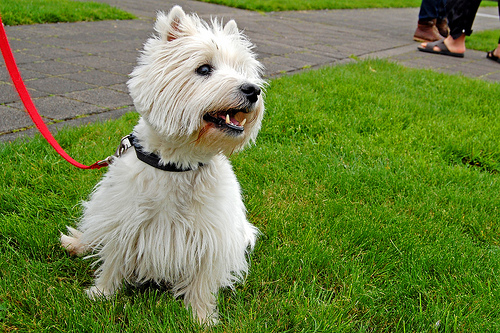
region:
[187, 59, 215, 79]
the dog's right eye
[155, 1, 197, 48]
the dog's right ear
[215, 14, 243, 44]
the dog's left ear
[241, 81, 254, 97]
the dog's right nostril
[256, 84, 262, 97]
the dog's left nostril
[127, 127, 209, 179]
the black collar around the dog's neck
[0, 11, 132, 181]
the red leash attached to the dog's collar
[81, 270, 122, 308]
the dog's front right paw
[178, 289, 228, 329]
the dog's front left paw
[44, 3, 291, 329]
a dog sitting in the grass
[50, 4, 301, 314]
a small dog sitting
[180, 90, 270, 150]
the mouth is open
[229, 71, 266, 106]
the nose is black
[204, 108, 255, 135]
two teeth are showing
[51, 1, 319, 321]
the dog is white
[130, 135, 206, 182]
the collar is black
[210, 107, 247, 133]
the tongue is pink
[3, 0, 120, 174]
the leash is red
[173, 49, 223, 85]
the eye is open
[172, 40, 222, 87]
the eye is black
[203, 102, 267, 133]
mouth of a dog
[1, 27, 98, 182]
red leash for the dog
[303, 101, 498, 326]
green grass on the ground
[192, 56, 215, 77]
right eye of the dog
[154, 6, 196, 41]
right ear of the dog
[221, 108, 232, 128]
bottom right tooth of dog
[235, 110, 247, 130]
bottom left tooth of dog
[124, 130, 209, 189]
black collar for the dog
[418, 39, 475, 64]
left food of a standing person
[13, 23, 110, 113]
concrete walkway for people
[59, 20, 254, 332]
white dog sitting in grass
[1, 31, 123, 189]
red leash of white dog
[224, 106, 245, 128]
white teeth of white dog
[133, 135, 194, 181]
black collar of dog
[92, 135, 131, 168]
silver latch on red leash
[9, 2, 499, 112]
sidewalk behind white dog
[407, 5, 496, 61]
two people standing on sidewalk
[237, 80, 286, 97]
black nose of white dog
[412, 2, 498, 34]
pants legs of two people on sidewalk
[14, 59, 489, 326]
patch of grass dog is sitting on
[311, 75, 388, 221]
this is the grass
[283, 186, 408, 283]
the grass is green in color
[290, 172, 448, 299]
the grass is short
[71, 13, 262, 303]
this is a dog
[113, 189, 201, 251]
the fur is white in color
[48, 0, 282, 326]
the dog is small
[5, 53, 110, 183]
this is a rope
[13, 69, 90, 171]
the rope is red in color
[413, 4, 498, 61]
these are people feet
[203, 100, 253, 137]
the dog's mouth is open